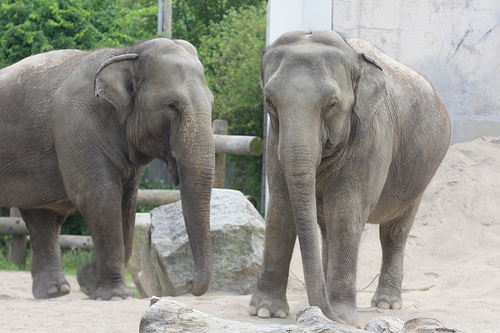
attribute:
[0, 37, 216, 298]
elephant — gray, standing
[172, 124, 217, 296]
trunk — gray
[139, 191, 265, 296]
rock — large, gray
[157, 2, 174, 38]
post — wood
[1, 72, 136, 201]
skin — wrinkled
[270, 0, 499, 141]
wall — gray